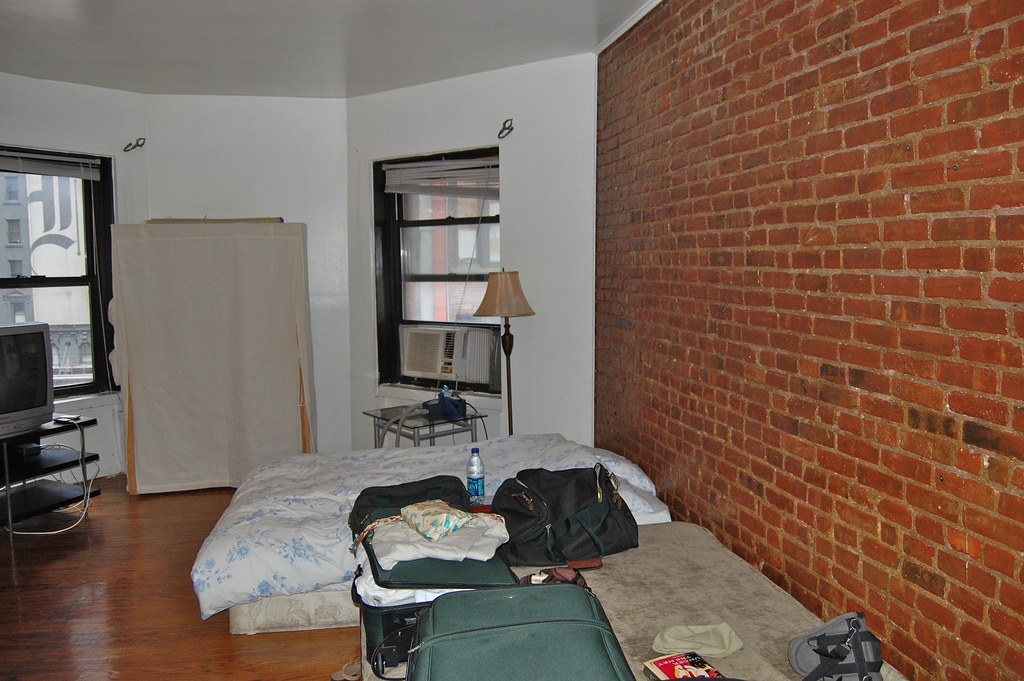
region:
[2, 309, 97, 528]
Television on a stand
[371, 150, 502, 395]
Air conditioner in window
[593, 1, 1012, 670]
Wall is made of bricks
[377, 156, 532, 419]
Lamp is near window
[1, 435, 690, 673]
bed sitting on floor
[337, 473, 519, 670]
suitcase full of clothes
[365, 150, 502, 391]
Blinds in the window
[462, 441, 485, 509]
Bottle near the bed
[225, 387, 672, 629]
Table is next to bed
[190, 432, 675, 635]
Comforter is on the bed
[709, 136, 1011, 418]
a brick wall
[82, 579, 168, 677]
a wooden floor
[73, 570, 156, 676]
the floor is wooden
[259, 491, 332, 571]
a comforter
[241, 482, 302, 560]
the comforter is white and blue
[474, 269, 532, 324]
a lamp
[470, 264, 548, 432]
a lamp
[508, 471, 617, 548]
a green bag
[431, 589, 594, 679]
the luggage is green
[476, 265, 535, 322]
brown lamp shade on the floor lamp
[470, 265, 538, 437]
floor lamp next to window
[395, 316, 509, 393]
air conditioner wall unit in the window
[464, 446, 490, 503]
plastic bottled water on the bed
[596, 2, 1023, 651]
a red brick wall in the apartment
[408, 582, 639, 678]
a green canvas suitcase with a zipper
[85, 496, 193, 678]
wood parquet floor in the apartment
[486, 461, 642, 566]
black canvas zippered duffle bag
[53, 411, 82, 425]
hand held remote controls on the TV stand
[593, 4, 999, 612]
wall is made of bricks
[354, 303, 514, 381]
air conditioner is in the window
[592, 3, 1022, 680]
the wall is made of brick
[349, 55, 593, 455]
a white painted wall is next to the brick wall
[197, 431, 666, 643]
a matress is on the floor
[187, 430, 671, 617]
there is a comforter on the mattress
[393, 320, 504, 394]
an air conditioner is in the window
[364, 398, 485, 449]
a night stand is next to the mattress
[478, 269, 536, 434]
a floor lamp is next to the mattress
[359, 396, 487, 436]
the nightstand is glass and metal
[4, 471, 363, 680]
the floor is wooden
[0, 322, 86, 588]
a tv is on top of a tv stand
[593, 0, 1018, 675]
Reddish brick wall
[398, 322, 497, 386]
rectangular white AC unit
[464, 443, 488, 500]
Bottle of water with blue cap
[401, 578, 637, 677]
A green suitcase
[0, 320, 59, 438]
An old model TV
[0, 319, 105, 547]
TV on the black TV stand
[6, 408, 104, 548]
Black TV stand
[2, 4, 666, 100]
a white ceiling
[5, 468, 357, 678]
a brown flooring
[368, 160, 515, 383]
a room window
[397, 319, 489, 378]
a window ac unit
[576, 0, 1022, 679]
a large brick wall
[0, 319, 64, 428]
a gray t.v.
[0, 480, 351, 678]
brown hardwood floor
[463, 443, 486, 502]
a tall plastic water bottle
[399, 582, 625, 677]
a large green suitcase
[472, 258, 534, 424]
a tall brown floor lamp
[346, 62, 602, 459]
a painted white wall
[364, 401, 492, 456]
a small gray side table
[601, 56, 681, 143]
red bricks forming a wall